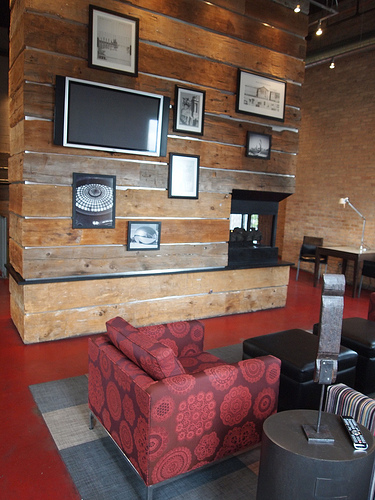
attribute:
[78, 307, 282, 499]
chair — red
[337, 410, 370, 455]
remote — black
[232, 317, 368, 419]
ottoman — black, dark colored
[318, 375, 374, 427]
sofa — striped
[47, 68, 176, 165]
tv — flat screen, mounted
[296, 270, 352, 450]
lamp — silver, modern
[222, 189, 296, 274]
fireplace — in room, black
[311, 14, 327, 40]
light — hanging, turned on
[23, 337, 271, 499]
carpet — grey, white, blue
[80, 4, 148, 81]
photo — framed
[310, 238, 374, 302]
table — in room, wood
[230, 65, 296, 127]
picture — black, white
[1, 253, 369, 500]
floor — red